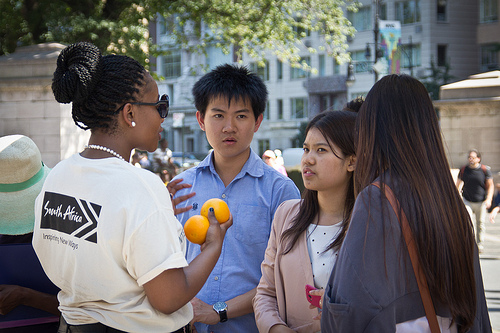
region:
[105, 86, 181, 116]
woman is wearing sun glasses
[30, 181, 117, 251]
black picture on shirt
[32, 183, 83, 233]
white letters on picture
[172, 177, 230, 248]
woman is holding oranges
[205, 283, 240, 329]
man is wearing a watch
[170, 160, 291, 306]
man's shirt is blue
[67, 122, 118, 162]
woman wearing a necklace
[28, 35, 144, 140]
woman has braids in hair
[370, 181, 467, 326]
woman carrying a bag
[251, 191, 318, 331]
woman's shirt is pink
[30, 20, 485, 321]
People are talking on a city street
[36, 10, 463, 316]
A person is holding some oranges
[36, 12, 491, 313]
Some friends are discussing their day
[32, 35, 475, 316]
Four friends are making plans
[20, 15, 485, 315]
A local is giving people directions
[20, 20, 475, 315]
A man is staring at something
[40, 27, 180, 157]
A person is wearing sunglasses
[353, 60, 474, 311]
A person has long dark hair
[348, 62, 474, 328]
A person has a strap over their shoulder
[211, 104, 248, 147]
The face of a person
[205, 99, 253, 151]
a face of a person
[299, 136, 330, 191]
the face of a person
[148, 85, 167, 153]
the profile of a face of a person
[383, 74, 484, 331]
long straight black hair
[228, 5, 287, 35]
the leaves of a tree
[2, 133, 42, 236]
a white hat with a green band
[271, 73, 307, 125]
the windows of a building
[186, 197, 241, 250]
a hand holding two oranges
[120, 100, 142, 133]
an ear of a person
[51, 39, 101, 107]
the bun of hair on a head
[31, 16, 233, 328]
lady holding two oranges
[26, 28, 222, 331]
lady wearing black sunglasses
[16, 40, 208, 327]
lady wearing braids in a bun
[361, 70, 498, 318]
long brown hair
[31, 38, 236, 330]
lady wearing a pearl necklace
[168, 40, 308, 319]
guy wit blue collared shirt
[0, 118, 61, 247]
beige and green sun hat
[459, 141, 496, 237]
men walking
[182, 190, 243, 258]
two oranges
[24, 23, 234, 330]
lady wearing a black and white tee shirt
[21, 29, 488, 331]
group of people standing and talking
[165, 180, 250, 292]
lady holding two oranges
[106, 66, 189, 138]
lady wearing sun glasses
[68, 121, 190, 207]
lady wearing pearls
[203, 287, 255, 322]
man wearing watch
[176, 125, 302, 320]
man wearing blue shirt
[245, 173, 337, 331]
lady wearing beige cardigan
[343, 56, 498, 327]
lady has very long hair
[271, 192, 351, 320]
lady wearing white shirt with black dots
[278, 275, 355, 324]
lady holding pink cell phone